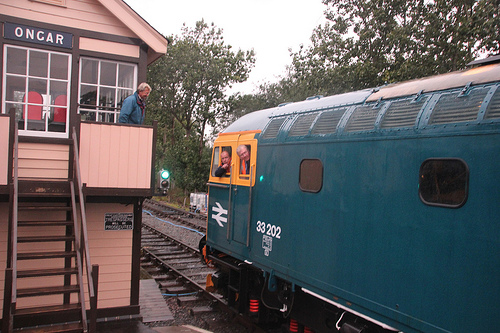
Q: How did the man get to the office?
A: Stairs.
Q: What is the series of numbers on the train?
A: 33 202.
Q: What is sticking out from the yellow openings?
A: Mens' heads.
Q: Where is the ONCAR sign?
A: Above the windows.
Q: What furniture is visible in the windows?
A: Chairs.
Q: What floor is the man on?
A: Second.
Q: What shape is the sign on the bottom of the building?
A: Rectangle.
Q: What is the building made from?
A: Wood.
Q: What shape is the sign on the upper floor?
A: Rectangle.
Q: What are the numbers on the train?
A: 33 202.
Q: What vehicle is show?
A: Train.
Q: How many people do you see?
A: Three.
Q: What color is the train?
A: Blue.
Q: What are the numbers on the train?
A: 33 202.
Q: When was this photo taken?
A: During the day.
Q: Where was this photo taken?
A: Outside at the train station.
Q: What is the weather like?
A: Chilly.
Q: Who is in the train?
A: Two people.